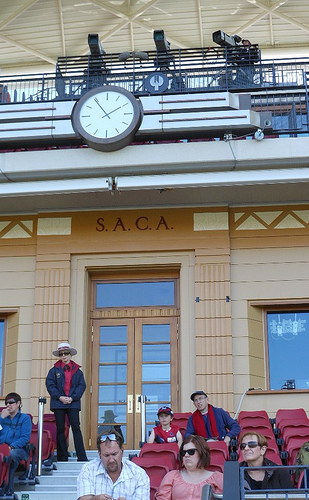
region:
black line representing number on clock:
[105, 92, 108, 101]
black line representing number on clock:
[112, 94, 121, 101]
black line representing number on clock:
[120, 99, 129, 109]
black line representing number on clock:
[122, 109, 132, 116]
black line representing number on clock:
[119, 120, 131, 127]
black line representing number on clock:
[113, 126, 120, 133]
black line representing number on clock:
[103, 128, 109, 137]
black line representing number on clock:
[92, 128, 100, 136]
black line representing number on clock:
[83, 122, 91, 129]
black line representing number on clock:
[84, 103, 93, 112]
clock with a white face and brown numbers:
[70, 84, 140, 150]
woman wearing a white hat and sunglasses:
[45, 340, 91, 460]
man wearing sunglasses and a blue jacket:
[0, 392, 29, 492]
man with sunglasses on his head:
[78, 427, 148, 498]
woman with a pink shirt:
[157, 433, 220, 498]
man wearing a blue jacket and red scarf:
[182, 389, 233, 442]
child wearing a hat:
[148, 406, 182, 447]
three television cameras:
[86, 27, 255, 83]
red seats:
[239, 409, 307, 431]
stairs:
[46, 459, 72, 497]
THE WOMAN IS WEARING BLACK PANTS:
[52, 398, 86, 461]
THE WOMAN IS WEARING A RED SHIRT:
[58, 357, 73, 398]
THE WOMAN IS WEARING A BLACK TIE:
[58, 362, 70, 374]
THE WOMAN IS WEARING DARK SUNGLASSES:
[55, 349, 69, 357]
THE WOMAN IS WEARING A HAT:
[44, 338, 77, 355]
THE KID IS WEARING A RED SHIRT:
[149, 421, 184, 446]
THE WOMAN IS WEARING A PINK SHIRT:
[154, 457, 234, 496]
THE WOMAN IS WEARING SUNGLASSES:
[177, 444, 200, 455]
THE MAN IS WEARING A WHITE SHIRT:
[72, 452, 153, 497]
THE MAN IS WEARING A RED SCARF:
[190, 401, 221, 440]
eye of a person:
[94, 445, 114, 464]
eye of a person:
[109, 444, 126, 458]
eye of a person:
[176, 444, 190, 455]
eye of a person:
[190, 444, 198, 454]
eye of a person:
[156, 408, 163, 419]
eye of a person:
[163, 410, 174, 419]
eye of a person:
[192, 394, 197, 401]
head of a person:
[226, 423, 271, 463]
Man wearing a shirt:
[74, 455, 156, 498]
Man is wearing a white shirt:
[73, 454, 152, 499]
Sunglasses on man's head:
[94, 431, 125, 445]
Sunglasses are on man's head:
[94, 431, 123, 445]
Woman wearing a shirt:
[153, 470, 230, 499]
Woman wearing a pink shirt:
[150, 466, 225, 498]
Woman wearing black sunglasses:
[178, 444, 200, 456]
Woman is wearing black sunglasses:
[177, 445, 205, 457]